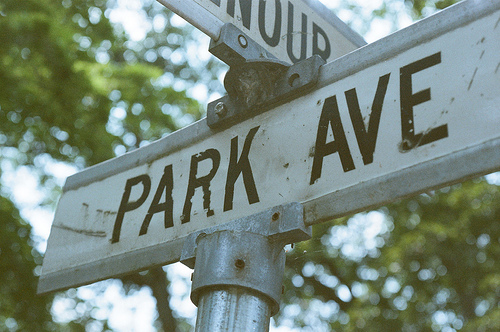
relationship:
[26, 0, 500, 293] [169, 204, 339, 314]
sign on pole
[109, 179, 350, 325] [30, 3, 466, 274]
pole with signs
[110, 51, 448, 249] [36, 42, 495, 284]
black letter on sign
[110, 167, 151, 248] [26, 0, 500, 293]
black letter on sign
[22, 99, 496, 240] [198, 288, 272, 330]
signboard on pole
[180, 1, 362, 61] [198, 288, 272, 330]
signboard on pole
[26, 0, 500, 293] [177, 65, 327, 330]
sign on pole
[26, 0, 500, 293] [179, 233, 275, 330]
sign on pole